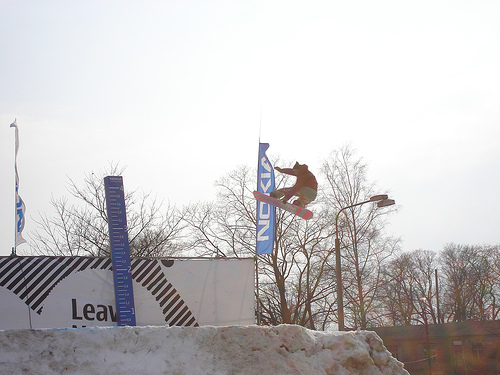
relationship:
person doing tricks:
[287, 166, 320, 203] [211, 167, 271, 202]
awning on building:
[378, 323, 444, 345] [404, 320, 479, 370]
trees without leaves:
[307, 263, 338, 291] [450, 251, 457, 259]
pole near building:
[355, 261, 372, 293] [404, 320, 479, 370]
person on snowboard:
[287, 166, 320, 203] [231, 199, 309, 218]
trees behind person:
[307, 263, 338, 291] [287, 166, 320, 203]